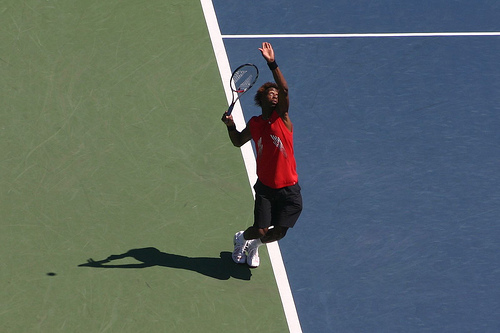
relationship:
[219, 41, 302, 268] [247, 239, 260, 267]
man wearing tennis shoes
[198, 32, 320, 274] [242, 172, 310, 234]
man wearing shorts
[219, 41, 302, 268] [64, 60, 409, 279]
man playing game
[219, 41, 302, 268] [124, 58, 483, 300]
man playing tennis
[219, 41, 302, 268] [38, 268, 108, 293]
man serving ball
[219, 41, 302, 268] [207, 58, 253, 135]
man holding racket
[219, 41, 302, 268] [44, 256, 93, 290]
man looking at ball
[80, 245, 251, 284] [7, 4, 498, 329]
shadow on court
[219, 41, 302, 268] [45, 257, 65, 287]
man serving ball